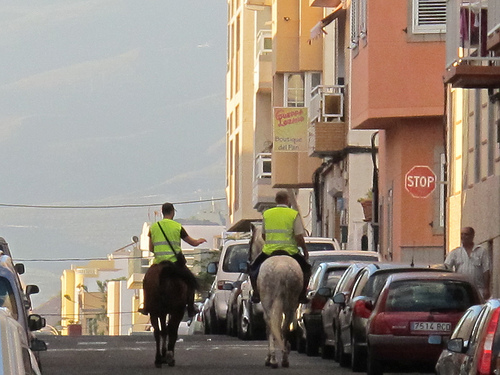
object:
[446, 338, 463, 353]
mirror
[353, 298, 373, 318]
mirror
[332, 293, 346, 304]
mirror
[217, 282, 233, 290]
mirror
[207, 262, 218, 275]
mirror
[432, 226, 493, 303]
man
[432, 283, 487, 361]
sidewalk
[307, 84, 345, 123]
balacony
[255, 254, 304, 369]
horse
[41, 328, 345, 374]
road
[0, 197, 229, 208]
line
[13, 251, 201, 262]
line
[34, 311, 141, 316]
line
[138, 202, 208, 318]
man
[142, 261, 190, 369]
black horse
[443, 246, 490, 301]
shirt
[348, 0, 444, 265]
building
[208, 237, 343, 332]
van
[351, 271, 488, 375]
hatchback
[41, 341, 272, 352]
white lines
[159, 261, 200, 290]
tail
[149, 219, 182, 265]
bright vest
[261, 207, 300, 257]
bright vest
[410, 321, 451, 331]
license plates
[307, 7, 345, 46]
awning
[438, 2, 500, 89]
patio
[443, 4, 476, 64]
railing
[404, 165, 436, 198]
sign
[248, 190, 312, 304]
horse rider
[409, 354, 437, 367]
curb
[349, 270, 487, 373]
car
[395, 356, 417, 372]
curb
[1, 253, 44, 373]
side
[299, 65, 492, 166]
second floor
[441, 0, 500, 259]
building